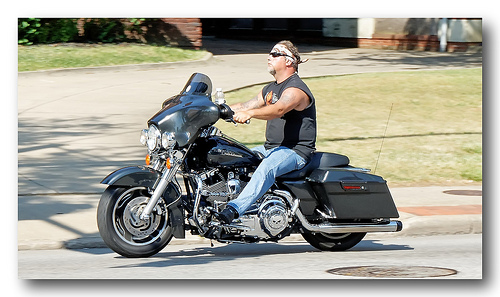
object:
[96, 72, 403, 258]
motorcycle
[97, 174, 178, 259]
tire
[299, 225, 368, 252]
tire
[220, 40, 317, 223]
man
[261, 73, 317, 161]
shirt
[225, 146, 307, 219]
pants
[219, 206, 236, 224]
shoe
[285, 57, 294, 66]
ear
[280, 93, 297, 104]
tattoo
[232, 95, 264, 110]
tattoo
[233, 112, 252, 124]
hand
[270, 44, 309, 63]
durag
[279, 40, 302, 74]
hair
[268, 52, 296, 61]
glasses